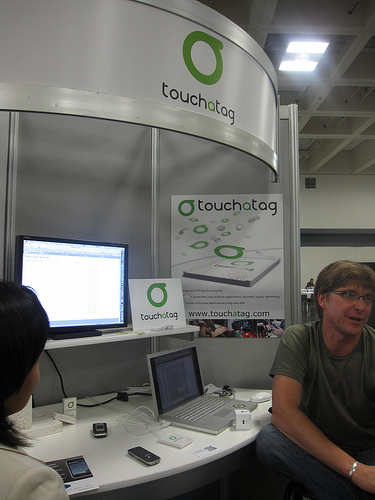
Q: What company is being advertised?
A: Touchatag.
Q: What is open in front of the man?
A: A laptop.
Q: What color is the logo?
A: Green.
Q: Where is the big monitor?
A: On a shelf.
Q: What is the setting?
A: A tradeshow.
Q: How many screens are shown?
A: Two.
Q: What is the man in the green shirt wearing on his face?
A: Glasses.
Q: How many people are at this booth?
A: Two.